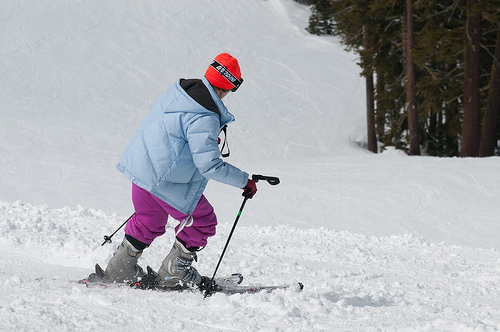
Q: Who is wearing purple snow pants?
A: Skier.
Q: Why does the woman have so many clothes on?
A: Keep warm.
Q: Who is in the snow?
A: A female.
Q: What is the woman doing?
A: Skiing.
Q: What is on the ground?
A: Snow.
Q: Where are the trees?
A: At the bottom of the hill.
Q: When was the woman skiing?
A: During daylight hours.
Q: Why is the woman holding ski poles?
A: She is skiing.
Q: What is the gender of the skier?
A: Female.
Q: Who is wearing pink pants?
A: A woman.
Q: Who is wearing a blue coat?
A: A female.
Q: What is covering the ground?
A: Snow.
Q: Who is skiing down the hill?
A: A woman.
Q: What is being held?
A: A ski pole.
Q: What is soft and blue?
A: Jacket.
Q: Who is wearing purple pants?
A: The skier.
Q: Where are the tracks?
A: In the snow.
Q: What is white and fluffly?
A: Snow.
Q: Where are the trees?
A: Along the slope.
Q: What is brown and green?
A: Trees.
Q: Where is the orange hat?
A: On the head.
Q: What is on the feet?
A: Boots.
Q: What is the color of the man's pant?
A: Is purple.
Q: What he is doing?
A: Skiing.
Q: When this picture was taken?
A: During the day.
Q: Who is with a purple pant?
A: A man.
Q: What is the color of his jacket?
A: Is blue and black.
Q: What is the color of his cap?
A: Is orange.